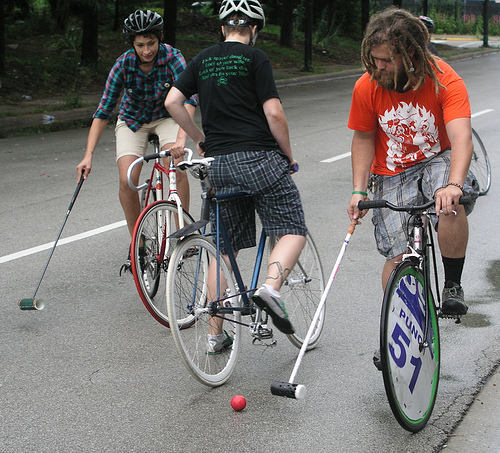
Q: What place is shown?
A: It is a pavement.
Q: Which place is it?
A: It is a pavement.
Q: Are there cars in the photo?
A: No, there are no cars.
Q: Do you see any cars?
A: No, there are no cars.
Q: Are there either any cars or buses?
A: No, there are no cars or buses.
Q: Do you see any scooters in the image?
A: No, there are no scooters.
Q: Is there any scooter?
A: No, there are no scooters.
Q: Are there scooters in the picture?
A: No, there are no scooters.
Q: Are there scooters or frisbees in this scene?
A: No, there are no scooters or frisbees.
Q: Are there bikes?
A: Yes, there is a bike.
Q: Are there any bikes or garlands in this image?
A: Yes, there is a bike.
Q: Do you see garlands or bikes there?
A: Yes, there is a bike.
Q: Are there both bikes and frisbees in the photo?
A: No, there is a bike but no frisbees.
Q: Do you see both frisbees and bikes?
A: No, there is a bike but no frisbees.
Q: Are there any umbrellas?
A: No, there are no umbrellas.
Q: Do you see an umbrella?
A: No, there are no umbrellas.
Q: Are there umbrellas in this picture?
A: No, there are no umbrellas.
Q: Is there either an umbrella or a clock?
A: No, there are no umbrellas or clocks.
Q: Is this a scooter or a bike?
A: This is a bike.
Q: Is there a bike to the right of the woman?
A: Yes, there is a bike to the right of the woman.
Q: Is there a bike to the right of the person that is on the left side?
A: Yes, there is a bike to the right of the woman.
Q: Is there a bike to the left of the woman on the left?
A: No, the bike is to the right of the woman.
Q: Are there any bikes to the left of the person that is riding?
A: No, the bike is to the right of the woman.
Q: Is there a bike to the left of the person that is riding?
A: No, the bike is to the right of the woman.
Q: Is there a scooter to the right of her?
A: No, there is a bike to the right of the woman.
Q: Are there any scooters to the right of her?
A: No, there is a bike to the right of the woman.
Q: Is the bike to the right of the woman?
A: Yes, the bike is to the right of the woman.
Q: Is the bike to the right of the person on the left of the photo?
A: Yes, the bike is to the right of the woman.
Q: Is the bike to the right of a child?
A: No, the bike is to the right of the woman.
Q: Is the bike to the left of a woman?
A: No, the bike is to the right of a woman.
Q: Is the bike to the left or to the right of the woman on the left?
A: The bike is to the right of the woman.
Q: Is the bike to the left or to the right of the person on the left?
A: The bike is to the right of the woman.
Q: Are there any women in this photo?
A: Yes, there is a woman.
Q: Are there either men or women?
A: Yes, there is a woman.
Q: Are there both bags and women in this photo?
A: No, there is a woman but no bags.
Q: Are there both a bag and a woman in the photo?
A: No, there is a woman but no bags.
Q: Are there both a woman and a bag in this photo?
A: No, there is a woman but no bags.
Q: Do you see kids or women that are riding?
A: Yes, the woman is riding.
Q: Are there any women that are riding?
A: Yes, there is a woman that is riding.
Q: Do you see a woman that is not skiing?
A: Yes, there is a woman that is riding .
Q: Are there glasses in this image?
A: No, there are no glasses.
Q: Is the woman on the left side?
A: Yes, the woman is on the left of the image.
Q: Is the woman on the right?
A: No, the woman is on the left of the image.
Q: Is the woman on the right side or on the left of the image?
A: The woman is on the left of the image.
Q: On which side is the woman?
A: The woman is on the left of the image.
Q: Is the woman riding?
A: Yes, the woman is riding.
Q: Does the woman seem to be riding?
A: Yes, the woman is riding.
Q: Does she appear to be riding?
A: Yes, the woman is riding.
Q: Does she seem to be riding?
A: Yes, the woman is riding.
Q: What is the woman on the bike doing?
A: The woman is riding.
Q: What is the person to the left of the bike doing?
A: The woman is riding.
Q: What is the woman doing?
A: The woman is riding.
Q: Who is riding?
A: The woman is riding.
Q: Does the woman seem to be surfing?
A: No, the woman is riding.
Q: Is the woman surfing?
A: No, the woman is riding.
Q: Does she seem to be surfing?
A: No, the woman is riding.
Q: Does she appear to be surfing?
A: No, the woman is riding.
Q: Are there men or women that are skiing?
A: No, there is a woman but she is riding.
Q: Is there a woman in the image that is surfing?
A: No, there is a woman but she is riding.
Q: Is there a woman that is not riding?
A: No, there is a woman but she is riding.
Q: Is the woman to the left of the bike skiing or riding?
A: The woman is riding.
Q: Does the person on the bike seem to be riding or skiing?
A: The woman is riding.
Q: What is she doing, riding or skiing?
A: The woman is riding.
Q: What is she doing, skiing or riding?
A: The woman is riding.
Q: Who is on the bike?
A: The woman is on the bike.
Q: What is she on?
A: The woman is on the bike.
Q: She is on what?
A: The woman is on the bike.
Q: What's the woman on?
A: The woman is on the bike.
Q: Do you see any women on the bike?
A: Yes, there is a woman on the bike.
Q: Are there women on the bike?
A: Yes, there is a woman on the bike.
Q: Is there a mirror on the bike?
A: No, there is a woman on the bike.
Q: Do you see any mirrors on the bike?
A: No, there is a woman on the bike.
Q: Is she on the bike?
A: Yes, the woman is on the bike.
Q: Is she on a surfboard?
A: No, the woman is on the bike.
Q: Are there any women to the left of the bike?
A: Yes, there is a woman to the left of the bike.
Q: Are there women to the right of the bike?
A: No, the woman is to the left of the bike.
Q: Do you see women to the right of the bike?
A: No, the woman is to the left of the bike.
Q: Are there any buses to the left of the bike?
A: No, there is a woman to the left of the bike.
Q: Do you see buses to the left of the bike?
A: No, there is a woman to the left of the bike.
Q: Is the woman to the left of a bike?
A: Yes, the woman is to the left of a bike.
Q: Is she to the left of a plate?
A: No, the woman is to the left of a bike.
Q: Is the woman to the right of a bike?
A: No, the woman is to the left of a bike.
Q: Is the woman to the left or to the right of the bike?
A: The woman is to the left of the bike.